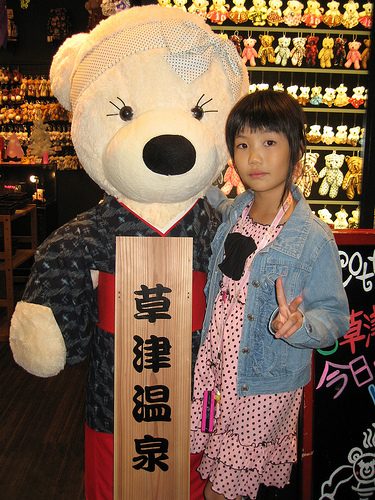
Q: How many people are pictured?
A: One.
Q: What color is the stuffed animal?
A: White.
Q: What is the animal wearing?
A: A kimono.